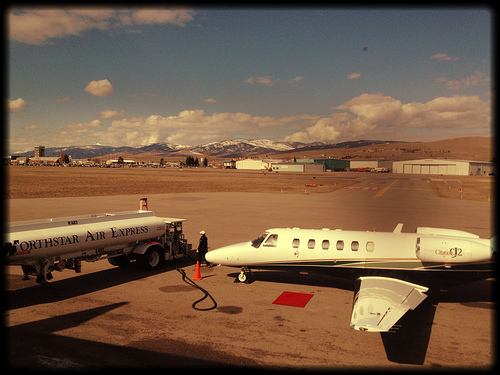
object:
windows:
[292, 238, 301, 248]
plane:
[204, 226, 493, 337]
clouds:
[11, 7, 196, 46]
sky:
[9, 8, 492, 145]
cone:
[191, 261, 203, 280]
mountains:
[15, 136, 405, 158]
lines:
[373, 179, 399, 198]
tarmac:
[8, 174, 491, 369]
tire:
[138, 244, 165, 273]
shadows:
[6, 298, 254, 371]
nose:
[202, 241, 254, 268]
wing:
[349, 275, 430, 333]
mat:
[272, 290, 315, 308]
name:
[19, 225, 150, 254]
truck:
[8, 215, 192, 285]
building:
[393, 157, 492, 177]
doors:
[403, 163, 457, 174]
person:
[196, 230, 210, 268]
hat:
[199, 230, 206, 234]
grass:
[6, 169, 359, 198]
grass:
[433, 176, 496, 202]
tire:
[237, 272, 249, 282]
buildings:
[234, 155, 352, 173]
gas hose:
[175, 267, 219, 311]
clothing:
[197, 235, 210, 266]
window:
[263, 234, 278, 248]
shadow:
[380, 291, 440, 366]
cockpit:
[250, 226, 279, 249]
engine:
[416, 235, 492, 265]